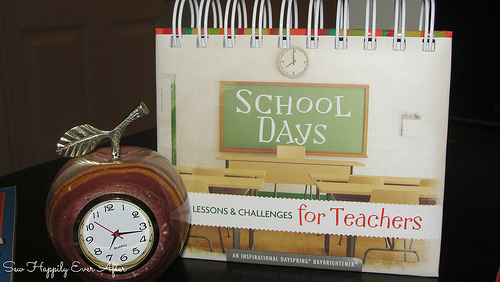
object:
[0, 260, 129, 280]
lettering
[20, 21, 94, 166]
door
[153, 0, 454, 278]
calendar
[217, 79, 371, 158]
chalkboard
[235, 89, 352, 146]
writing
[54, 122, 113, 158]
leaf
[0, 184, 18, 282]
corner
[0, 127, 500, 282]
desk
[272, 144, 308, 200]
chair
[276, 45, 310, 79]
clock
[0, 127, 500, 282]
black table-top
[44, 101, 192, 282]
apple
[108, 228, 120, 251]
hand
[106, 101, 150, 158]
stem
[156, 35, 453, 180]
wall